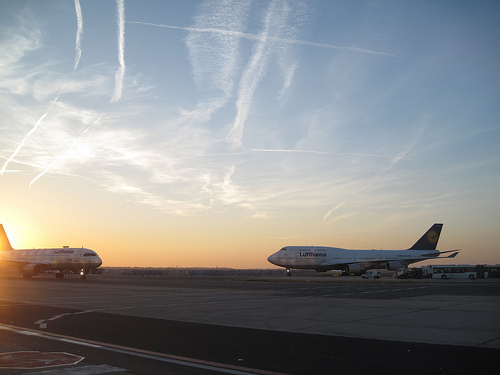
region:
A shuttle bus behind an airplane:
[426, 263, 486, 283]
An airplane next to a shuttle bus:
[264, 220, 464, 277]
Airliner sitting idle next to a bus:
[261, 221, 465, 281]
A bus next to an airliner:
[421, 263, 493, 276]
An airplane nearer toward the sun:
[0, 222, 105, 284]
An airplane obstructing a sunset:
[0, 220, 106, 280]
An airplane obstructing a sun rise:
[0, 222, 109, 282]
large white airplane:
[265, 222, 459, 277]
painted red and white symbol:
[2, 346, 83, 373]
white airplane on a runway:
[0, 220, 101, 282]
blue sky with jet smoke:
[5, 1, 499, 232]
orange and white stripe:
[2, 320, 281, 373]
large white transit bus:
[428, 260, 488, 281]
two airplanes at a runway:
[0, 216, 456, 285]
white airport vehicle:
[360, 266, 382, 280]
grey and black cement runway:
[2, 278, 496, 374]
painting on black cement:
[0, 317, 287, 372]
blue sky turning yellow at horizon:
[3, 7, 495, 265]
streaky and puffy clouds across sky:
[5, 11, 485, 218]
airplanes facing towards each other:
[5, 219, 460, 281]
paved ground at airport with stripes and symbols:
[2, 265, 493, 368]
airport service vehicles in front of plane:
[265, 215, 487, 283]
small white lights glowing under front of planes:
[71, 242, 298, 280]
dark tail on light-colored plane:
[263, 220, 460, 286]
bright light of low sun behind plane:
[3, 220, 103, 281]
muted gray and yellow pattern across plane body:
[4, 243, 102, 270]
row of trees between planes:
[78, 243, 348, 285]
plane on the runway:
[267, 216, 466, 283]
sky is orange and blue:
[2, 200, 266, 279]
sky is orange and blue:
[114, 137, 239, 279]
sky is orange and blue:
[107, 199, 232, 284]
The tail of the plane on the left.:
[0, 228, 12, 255]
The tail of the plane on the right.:
[420, 223, 447, 247]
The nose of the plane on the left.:
[95, 256, 103, 263]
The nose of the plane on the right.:
[267, 255, 275, 266]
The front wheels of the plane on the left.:
[77, 268, 87, 278]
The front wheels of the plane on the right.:
[280, 265, 292, 276]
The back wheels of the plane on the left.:
[50, 265, 67, 277]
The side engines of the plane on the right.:
[342, 260, 407, 277]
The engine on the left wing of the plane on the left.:
[17, 265, 42, 273]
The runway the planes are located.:
[6, 260, 484, 372]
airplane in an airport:
[261, 215, 463, 290]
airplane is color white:
[258, 219, 463, 297]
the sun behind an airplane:
[1, 204, 106, 289]